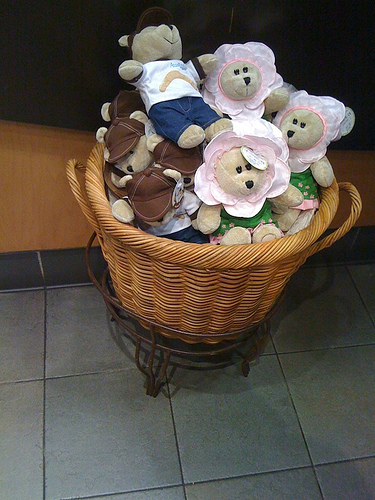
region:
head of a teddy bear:
[217, 140, 274, 193]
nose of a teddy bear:
[239, 181, 260, 190]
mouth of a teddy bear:
[233, 183, 264, 202]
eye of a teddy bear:
[247, 156, 262, 174]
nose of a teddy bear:
[122, 160, 143, 181]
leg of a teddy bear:
[113, 196, 145, 230]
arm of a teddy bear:
[195, 203, 234, 238]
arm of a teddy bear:
[262, 182, 313, 215]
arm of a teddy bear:
[304, 147, 345, 189]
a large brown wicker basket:
[62, 123, 360, 346]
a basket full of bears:
[65, 8, 359, 346]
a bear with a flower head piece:
[191, 127, 299, 248]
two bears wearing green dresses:
[196, 94, 335, 245]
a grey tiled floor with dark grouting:
[2, 266, 373, 499]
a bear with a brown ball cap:
[115, 166, 202, 245]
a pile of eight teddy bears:
[99, 8, 354, 246]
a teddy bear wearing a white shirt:
[116, 6, 232, 146]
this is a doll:
[105, 14, 215, 152]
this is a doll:
[128, 164, 189, 235]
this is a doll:
[102, 107, 162, 183]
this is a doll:
[195, 38, 285, 123]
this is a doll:
[275, 144, 321, 224]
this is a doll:
[141, 85, 275, 185]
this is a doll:
[208, 113, 308, 208]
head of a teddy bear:
[122, 14, 181, 68]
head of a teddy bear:
[218, 132, 277, 200]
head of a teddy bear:
[271, 103, 333, 152]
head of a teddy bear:
[97, 123, 152, 190]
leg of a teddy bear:
[103, 177, 152, 230]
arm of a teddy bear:
[198, 196, 241, 236]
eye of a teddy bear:
[235, 161, 248, 177]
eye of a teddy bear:
[246, 155, 261, 168]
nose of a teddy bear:
[122, 152, 139, 171]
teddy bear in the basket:
[204, 133, 299, 248]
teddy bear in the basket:
[123, 163, 203, 248]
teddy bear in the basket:
[275, 92, 335, 216]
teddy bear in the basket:
[120, 14, 224, 142]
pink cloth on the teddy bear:
[197, 129, 274, 214]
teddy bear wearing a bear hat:
[96, 113, 147, 159]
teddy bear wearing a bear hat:
[104, 88, 145, 123]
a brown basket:
[55, 136, 367, 350]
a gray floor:
[3, 282, 372, 494]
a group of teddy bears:
[91, 22, 354, 251]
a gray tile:
[38, 362, 185, 493]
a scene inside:
[32, 94, 368, 334]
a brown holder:
[75, 245, 293, 392]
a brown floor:
[4, 117, 369, 255]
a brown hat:
[112, 165, 182, 220]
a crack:
[156, 359, 192, 488]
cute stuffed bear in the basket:
[188, 126, 298, 246]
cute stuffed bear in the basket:
[109, 164, 203, 249]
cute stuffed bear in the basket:
[153, 137, 213, 203]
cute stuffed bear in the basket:
[91, 112, 169, 190]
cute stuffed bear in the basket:
[93, 85, 151, 131]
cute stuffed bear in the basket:
[113, 5, 233, 145]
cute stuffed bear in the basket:
[195, 41, 289, 125]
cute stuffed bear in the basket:
[257, 85, 355, 231]